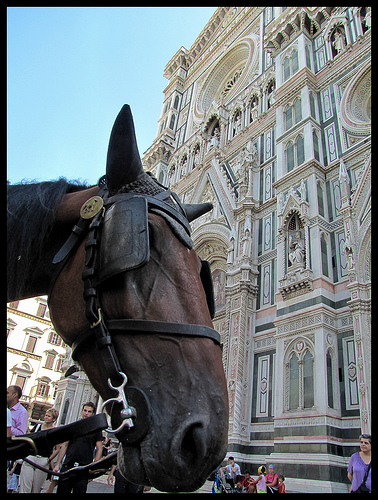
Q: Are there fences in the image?
A: No, there are no fences.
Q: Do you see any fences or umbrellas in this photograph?
A: No, there are no fences or umbrellas.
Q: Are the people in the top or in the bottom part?
A: The people are in the bottom of the image.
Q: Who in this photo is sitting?
A: The people are sitting.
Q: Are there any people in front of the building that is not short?
A: Yes, there are people in front of the building.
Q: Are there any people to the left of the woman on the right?
A: Yes, there are people to the left of the woman.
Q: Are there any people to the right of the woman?
A: No, the people are to the left of the woman.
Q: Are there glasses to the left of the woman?
A: No, there are people to the left of the woman.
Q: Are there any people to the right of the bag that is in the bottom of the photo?
A: No, the people are to the left of the bag.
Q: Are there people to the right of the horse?
A: Yes, there are people to the right of the horse.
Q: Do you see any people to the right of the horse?
A: Yes, there are people to the right of the horse.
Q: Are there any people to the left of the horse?
A: No, the people are to the right of the horse.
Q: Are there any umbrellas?
A: No, there are no umbrellas.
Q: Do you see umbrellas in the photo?
A: No, there are no umbrellas.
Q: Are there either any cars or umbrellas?
A: No, there are no umbrellas or cars.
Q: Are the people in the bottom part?
A: Yes, the people are in the bottom of the image.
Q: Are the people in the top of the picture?
A: No, the people are in the bottom of the image.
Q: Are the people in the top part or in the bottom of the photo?
A: The people are in the bottom of the image.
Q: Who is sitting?
A: The people are sitting.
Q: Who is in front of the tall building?
A: The people are in front of the building.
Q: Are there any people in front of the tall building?
A: Yes, there are people in front of the building.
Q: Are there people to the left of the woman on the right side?
A: Yes, there are people to the left of the woman.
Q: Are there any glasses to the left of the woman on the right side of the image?
A: No, there are people to the left of the woman.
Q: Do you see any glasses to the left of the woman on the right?
A: No, there are people to the left of the woman.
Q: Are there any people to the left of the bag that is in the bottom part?
A: Yes, there are people to the left of the bag.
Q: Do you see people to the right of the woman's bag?
A: No, the people are to the left of the bag.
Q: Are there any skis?
A: No, there are no skis.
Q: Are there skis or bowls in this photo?
A: No, there are no skis or bowls.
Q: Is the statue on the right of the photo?
A: Yes, the statue is on the right of the image.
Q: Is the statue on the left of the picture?
A: No, the statue is on the right of the image.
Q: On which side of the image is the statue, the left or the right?
A: The statue is on the right of the image.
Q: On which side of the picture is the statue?
A: The statue is on the right of the image.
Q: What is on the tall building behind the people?
A: The statue is on the building.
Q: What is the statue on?
A: The statue is on the building.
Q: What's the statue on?
A: The statue is on the building.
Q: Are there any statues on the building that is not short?
A: Yes, there is a statue on the building.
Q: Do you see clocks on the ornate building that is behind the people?
A: No, there is a statue on the building.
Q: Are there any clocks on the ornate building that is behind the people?
A: No, there is a statue on the building.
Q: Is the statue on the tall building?
A: Yes, the statue is on the building.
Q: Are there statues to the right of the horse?
A: Yes, there is a statue to the right of the horse.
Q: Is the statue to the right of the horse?
A: Yes, the statue is to the right of the horse.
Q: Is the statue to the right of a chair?
A: No, the statue is to the right of the horse.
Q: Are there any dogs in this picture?
A: No, there are no dogs.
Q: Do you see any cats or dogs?
A: No, there are no dogs or cats.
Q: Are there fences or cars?
A: No, there are no cars or fences.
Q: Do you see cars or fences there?
A: No, there are no cars or fences.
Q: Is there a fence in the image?
A: No, there are no fences.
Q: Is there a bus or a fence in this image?
A: No, there are no fences or buses.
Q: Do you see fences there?
A: No, there are no fences.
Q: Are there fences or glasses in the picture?
A: No, there are no fences or glasses.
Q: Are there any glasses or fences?
A: No, there are no fences or glasses.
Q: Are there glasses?
A: No, there are no glasses.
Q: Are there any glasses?
A: No, there are no glasses.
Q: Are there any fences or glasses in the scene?
A: No, there are no glasses or fences.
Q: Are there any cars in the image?
A: No, there are no cars.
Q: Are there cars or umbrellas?
A: No, there are no cars or umbrellas.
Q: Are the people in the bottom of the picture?
A: Yes, the people are in the bottom of the image.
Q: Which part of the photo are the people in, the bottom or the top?
A: The people are in the bottom of the image.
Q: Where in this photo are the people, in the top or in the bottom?
A: The people are in the bottom of the image.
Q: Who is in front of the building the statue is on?
A: The people are in front of the building.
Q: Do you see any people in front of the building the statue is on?
A: Yes, there are people in front of the building.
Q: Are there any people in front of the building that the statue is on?
A: Yes, there are people in front of the building.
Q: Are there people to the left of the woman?
A: Yes, there are people to the left of the woman.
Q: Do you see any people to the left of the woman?
A: Yes, there are people to the left of the woman.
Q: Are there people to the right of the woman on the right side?
A: No, the people are to the left of the woman.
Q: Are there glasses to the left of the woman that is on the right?
A: No, there are people to the left of the woman.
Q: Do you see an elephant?
A: No, there are no elephants.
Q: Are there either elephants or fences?
A: No, there are no elephants or fences.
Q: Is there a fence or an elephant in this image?
A: No, there are no elephants or fences.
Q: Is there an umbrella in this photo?
A: No, there are no umbrellas.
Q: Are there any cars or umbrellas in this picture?
A: No, there are no umbrellas or cars.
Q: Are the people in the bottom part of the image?
A: Yes, the people are in the bottom of the image.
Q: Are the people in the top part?
A: No, the people are in the bottom of the image.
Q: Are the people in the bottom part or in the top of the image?
A: The people are in the bottom of the image.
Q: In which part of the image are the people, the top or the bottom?
A: The people are in the bottom of the image.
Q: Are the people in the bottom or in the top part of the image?
A: The people are in the bottom of the image.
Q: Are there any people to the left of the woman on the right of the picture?
A: Yes, there are people to the left of the woman.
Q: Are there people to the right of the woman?
A: No, the people are to the left of the woman.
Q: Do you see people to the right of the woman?
A: No, the people are to the left of the woman.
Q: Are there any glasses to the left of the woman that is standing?
A: No, there are people to the left of the woman.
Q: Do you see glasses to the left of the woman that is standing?
A: No, there are people to the left of the woman.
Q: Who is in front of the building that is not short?
A: The people are in front of the building.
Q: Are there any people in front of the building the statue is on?
A: Yes, there are people in front of the building.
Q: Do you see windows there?
A: Yes, there is a window.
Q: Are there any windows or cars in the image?
A: Yes, there is a window.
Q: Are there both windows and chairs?
A: No, there is a window but no chairs.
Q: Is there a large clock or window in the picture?
A: Yes, there is a large window.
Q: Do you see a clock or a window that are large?
A: Yes, the window is large.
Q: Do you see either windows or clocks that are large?
A: Yes, the window is large.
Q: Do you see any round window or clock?
A: Yes, there is a round window.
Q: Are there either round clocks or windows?
A: Yes, there is a round window.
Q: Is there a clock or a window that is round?
A: Yes, the window is round.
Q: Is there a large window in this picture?
A: Yes, there is a large window.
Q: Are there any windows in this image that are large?
A: Yes, there is a window that is large.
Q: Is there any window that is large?
A: Yes, there is a window that is large.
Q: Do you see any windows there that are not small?
A: Yes, there is a large window.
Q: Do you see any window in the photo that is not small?
A: Yes, there is a large window.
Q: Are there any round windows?
A: Yes, there is a round window.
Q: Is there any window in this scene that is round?
A: Yes, there is a window that is round.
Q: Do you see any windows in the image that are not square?
A: Yes, there is a round window.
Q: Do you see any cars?
A: No, there are no cars.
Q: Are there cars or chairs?
A: No, there are no cars or chairs.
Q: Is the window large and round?
A: Yes, the window is large and round.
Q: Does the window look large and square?
A: No, the window is large but round.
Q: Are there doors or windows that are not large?
A: No, there is a window but it is large.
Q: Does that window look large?
A: Yes, the window is large.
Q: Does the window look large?
A: Yes, the window is large.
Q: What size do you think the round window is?
A: The window is large.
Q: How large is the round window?
A: The window is large.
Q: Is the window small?
A: No, the window is large.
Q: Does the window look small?
A: No, the window is large.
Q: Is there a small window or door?
A: No, there is a window but it is large.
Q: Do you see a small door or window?
A: No, there is a window but it is large.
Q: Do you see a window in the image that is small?
A: No, there is a window but it is large.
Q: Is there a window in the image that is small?
A: No, there is a window but it is large.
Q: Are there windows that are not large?
A: No, there is a window but it is large.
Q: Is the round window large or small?
A: The window is large.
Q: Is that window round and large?
A: Yes, the window is round and large.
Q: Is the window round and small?
A: No, the window is round but large.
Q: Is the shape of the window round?
A: Yes, the window is round.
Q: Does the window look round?
A: Yes, the window is round.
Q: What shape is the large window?
A: The window is round.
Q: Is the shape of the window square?
A: No, the window is round.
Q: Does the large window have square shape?
A: No, the window is round.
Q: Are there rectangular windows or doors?
A: No, there is a window but it is round.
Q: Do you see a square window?
A: No, there is a window but it is round.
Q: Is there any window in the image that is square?
A: No, there is a window but it is round.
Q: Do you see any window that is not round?
A: No, there is a window but it is round.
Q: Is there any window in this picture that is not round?
A: No, there is a window but it is round.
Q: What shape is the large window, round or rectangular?
A: The window is round.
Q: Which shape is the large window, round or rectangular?
A: The window is round.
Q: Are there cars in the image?
A: No, there are no cars.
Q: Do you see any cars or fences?
A: No, there are no cars or fences.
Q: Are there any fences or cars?
A: No, there are no cars or fences.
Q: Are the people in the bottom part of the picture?
A: Yes, the people are in the bottom of the image.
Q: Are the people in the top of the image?
A: No, the people are in the bottom of the image.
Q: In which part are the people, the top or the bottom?
A: The people are in the bottom of the image.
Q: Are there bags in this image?
A: Yes, there is a bag.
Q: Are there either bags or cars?
A: Yes, there is a bag.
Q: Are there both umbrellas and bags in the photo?
A: No, there is a bag but no umbrellas.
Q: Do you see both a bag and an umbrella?
A: No, there is a bag but no umbrellas.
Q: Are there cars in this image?
A: No, there are no cars.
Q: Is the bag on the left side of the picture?
A: No, the bag is on the right of the image.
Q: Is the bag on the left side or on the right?
A: The bag is on the right of the image.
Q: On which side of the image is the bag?
A: The bag is on the right of the image.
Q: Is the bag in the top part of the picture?
A: No, the bag is in the bottom of the image.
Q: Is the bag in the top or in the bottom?
A: The bag is in the bottom of the image.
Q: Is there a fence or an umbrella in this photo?
A: No, there are no umbrellas or fences.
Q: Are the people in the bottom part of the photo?
A: Yes, the people are in the bottom of the image.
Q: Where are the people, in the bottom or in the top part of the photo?
A: The people are in the bottom of the image.